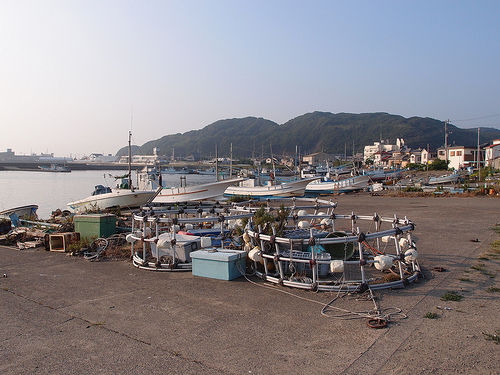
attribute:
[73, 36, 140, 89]
clouds — white 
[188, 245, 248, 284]
container — blue 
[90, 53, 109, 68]
clouds — white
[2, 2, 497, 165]
sky — blue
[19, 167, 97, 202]
water — calm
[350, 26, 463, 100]
sky — blue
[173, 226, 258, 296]
box — blue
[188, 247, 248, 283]
box — blue